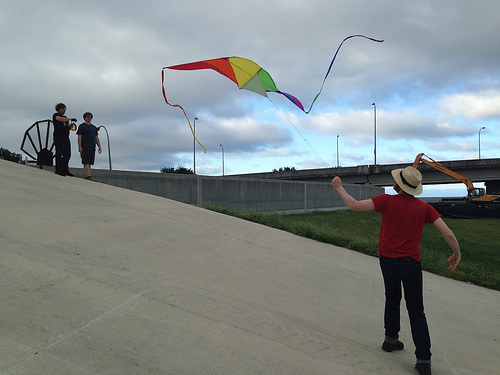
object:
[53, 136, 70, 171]
pants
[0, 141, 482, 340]
park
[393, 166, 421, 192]
head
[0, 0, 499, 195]
sky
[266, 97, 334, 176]
rope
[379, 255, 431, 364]
pants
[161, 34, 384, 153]
kite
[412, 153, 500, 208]
crane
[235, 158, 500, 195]
bridge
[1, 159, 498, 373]
slope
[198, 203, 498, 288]
yard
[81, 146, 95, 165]
clothing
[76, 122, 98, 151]
clothing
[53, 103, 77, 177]
adult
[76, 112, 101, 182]
adult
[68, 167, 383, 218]
fence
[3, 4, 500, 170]
clouds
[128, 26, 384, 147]
object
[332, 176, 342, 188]
hand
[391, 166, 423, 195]
cap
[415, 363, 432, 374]
shoe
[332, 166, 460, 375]
boy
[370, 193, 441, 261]
shirt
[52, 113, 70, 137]
clothes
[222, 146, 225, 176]
posts